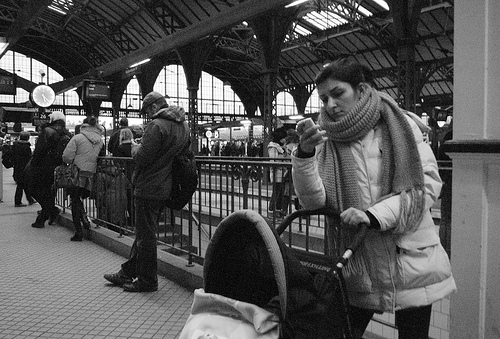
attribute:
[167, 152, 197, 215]
bag — black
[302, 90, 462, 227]
scarf — fringed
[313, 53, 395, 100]
hair — dark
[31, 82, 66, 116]
clock — glowing, white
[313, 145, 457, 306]
jacket — white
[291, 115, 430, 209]
jacket — puffed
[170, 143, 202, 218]
backpack — black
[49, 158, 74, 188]
purse — large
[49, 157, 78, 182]
purse — large